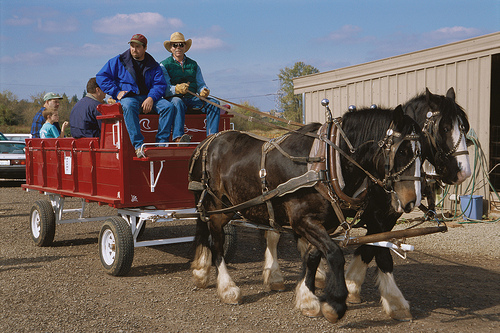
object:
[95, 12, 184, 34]
cloud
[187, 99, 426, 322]
horses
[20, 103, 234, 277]
cart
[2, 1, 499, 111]
sky